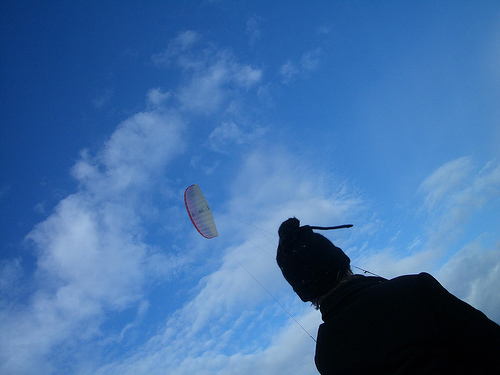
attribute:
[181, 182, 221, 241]
parasail — is large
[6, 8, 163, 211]
sky — blue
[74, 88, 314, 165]
sky — blue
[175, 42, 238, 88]
cloud — white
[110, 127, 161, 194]
cloud — white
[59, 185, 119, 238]
cloud — white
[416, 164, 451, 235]
cloud — white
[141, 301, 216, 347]
cloud — white